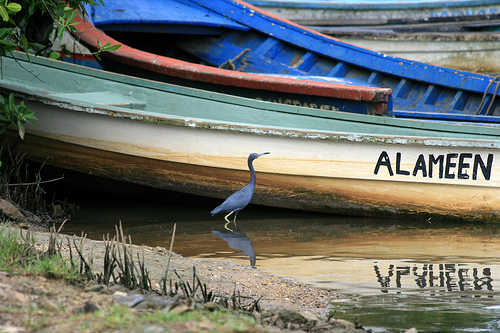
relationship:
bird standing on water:
[211, 152, 272, 232] [300, 222, 435, 287]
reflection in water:
[214, 227, 260, 266] [49, 183, 498, 331]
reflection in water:
[370, 252, 499, 301] [1, 174, 498, 329]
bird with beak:
[206, 143, 282, 234] [256, 142, 271, 162]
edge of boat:
[157, 69, 399, 101] [2, 57, 499, 234]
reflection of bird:
[214, 227, 260, 266] [206, 146, 274, 223]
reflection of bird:
[214, 227, 260, 266] [211, 150, 268, 229]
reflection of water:
[370, 252, 499, 301] [30, 176, 499, 318]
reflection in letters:
[370, 252, 499, 301] [373, 147, 496, 181]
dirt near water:
[92, 239, 313, 296] [266, 199, 494, 266]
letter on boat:
[473, 155, 492, 181] [5, 50, 496, 216]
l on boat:
[394, 151, 411, 176] [0, 0, 498, 222]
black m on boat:
[430, 149, 449, 182] [95, 65, 492, 237]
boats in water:
[10, 3, 498, 224] [301, 211, 494, 320]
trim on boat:
[61, 5, 390, 111] [58, 2, 498, 132]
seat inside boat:
[58, 84, 134, 105] [83, 111, 484, 170]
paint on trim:
[310, 134, 496, 146] [0, 45, 499, 156]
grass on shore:
[2, 225, 64, 274] [5, 222, 373, 332]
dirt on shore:
[0, 228, 312, 333] [5, 222, 373, 332]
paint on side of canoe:
[142, 41, 384, 106] [64, 10, 463, 105]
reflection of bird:
[214, 227, 260, 266] [205, 150, 270, 226]